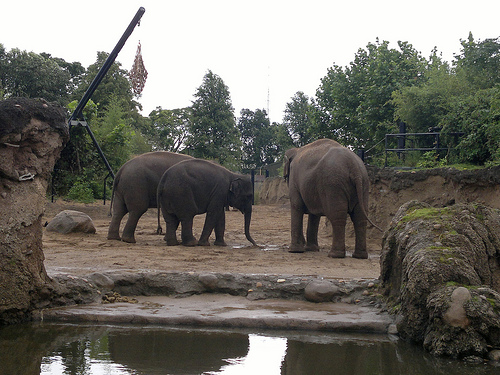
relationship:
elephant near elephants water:
[157, 158, 258, 246] [2, 319, 499, 374]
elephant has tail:
[283, 138, 383, 259] [332, 149, 390, 257]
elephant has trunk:
[157, 158, 258, 246] [238, 205, 257, 245]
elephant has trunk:
[107, 151, 221, 243] [242, 208, 264, 247]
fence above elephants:
[378, 126, 471, 166] [106, 118, 395, 258]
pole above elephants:
[55, 6, 164, 127] [82, 110, 372, 269]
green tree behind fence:
[0, 38, 498, 162] [385, 134, 448, 166]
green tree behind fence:
[320, 38, 428, 143] [385, 134, 448, 166]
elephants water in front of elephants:
[2, 319, 499, 374] [101, 122, 378, 254]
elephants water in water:
[2, 319, 499, 374] [16, 306, 358, 373]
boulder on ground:
[42, 207, 98, 247] [58, 203, 193, 262]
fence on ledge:
[385, 122, 464, 170] [368, 157, 498, 188]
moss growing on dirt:
[395, 199, 485, 260] [371, 223, 433, 313]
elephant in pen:
[283, 138, 383, 259] [76, 225, 431, 285]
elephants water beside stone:
[2, 319, 499, 374] [375, 196, 498, 372]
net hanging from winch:
[125, 46, 147, 101] [71, 4, 143, 189]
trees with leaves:
[320, 40, 498, 160] [333, 46, 429, 146]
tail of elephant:
[151, 193, 166, 244] [157, 158, 258, 246]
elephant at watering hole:
[283, 138, 383, 259] [236, 242, 290, 251]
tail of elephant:
[347, 172, 381, 236] [279, 135, 372, 259]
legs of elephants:
[100, 191, 147, 243] [101, 142, 268, 259]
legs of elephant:
[289, 212, 317, 255] [285, 134, 363, 263]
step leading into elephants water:
[35, 292, 392, 332] [2, 319, 499, 374]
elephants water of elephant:
[2, 319, 499, 374] [283, 138, 383, 259]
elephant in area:
[281, 135, 386, 265] [64, 151, 402, 278]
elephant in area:
[152, 153, 265, 253] [64, 151, 402, 278]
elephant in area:
[102, 147, 207, 244] [64, 151, 402, 278]